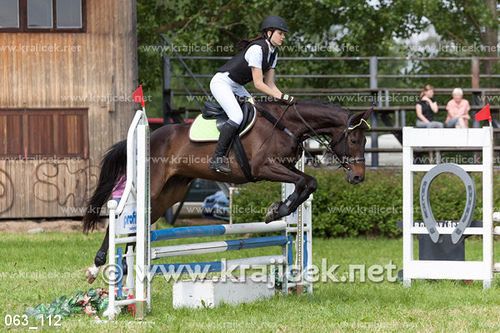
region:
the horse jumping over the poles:
[80, 25, 371, 291]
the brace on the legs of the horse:
[275, 188, 305, 220]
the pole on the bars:
[152, 222, 283, 270]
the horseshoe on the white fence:
[418, 163, 477, 243]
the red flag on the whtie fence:
[475, 100, 493, 130]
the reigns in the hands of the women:
[280, 88, 300, 114]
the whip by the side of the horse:
[255, 97, 291, 154]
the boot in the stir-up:
[205, 118, 242, 176]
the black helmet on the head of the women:
[261, 12, 282, 34]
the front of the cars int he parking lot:
[200, 191, 232, 222]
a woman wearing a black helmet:
[254, 4, 298, 76]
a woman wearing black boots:
[188, 25, 303, 179]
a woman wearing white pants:
[181, 15, 300, 150]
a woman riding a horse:
[108, 5, 383, 245]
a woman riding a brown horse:
[98, 13, 405, 258]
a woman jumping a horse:
[96, 3, 388, 260]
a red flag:
[108, 76, 166, 128]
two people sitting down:
[390, 69, 491, 145]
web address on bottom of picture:
[100, 254, 411, 294]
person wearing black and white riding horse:
[203, 11, 303, 177]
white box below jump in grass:
[168, 265, 300, 315]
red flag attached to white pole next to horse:
[126, 81, 154, 118]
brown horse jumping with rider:
[62, 11, 392, 286]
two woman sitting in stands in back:
[401, 76, 480, 131]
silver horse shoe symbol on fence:
[416, 152, 478, 248]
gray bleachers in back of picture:
[156, 34, 498, 186]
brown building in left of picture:
[2, 3, 147, 221]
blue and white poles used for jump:
[144, 208, 297, 284]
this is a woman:
[188, 17, 322, 184]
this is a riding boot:
[205, 116, 247, 173]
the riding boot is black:
[203, 104, 245, 182]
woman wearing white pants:
[202, 67, 251, 127]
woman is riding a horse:
[88, 1, 382, 262]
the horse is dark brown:
[86, 36, 365, 270]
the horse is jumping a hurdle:
[85, 38, 408, 316]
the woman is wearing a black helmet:
[257, 14, 297, 50]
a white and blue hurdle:
[83, 92, 347, 307]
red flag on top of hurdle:
[125, 70, 169, 147]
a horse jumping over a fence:
[107, 25, 344, 286]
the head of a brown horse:
[327, 92, 378, 182]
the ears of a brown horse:
[340, 101, 377, 132]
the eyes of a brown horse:
[340, 130, 369, 150]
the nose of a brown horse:
[342, 169, 364, 178]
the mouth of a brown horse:
[345, 167, 355, 182]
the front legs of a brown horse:
[257, 159, 325, 207]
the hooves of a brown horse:
[244, 197, 288, 224]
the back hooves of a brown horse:
[80, 248, 110, 284]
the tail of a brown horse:
[83, 129, 128, 211]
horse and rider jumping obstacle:
[100, 9, 374, 220]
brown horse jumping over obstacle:
[168, 100, 384, 222]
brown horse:
[168, 95, 380, 227]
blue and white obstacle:
[120, 218, 322, 305]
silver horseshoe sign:
[410, 158, 485, 253]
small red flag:
[123, 82, 148, 111]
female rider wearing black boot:
[213, 118, 245, 175]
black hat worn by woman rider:
[255, 6, 287, 31]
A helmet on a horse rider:
[256, 15, 287, 33]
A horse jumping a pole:
[80, 103, 367, 283]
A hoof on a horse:
[85, 262, 98, 282]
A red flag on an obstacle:
[475, 102, 492, 124]